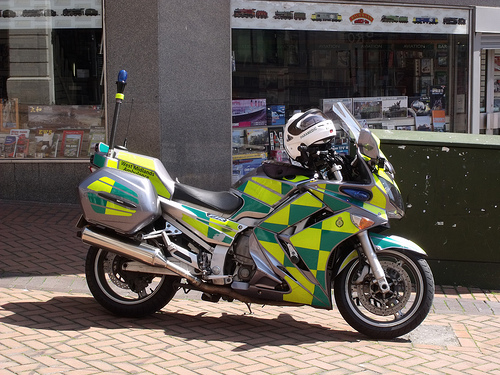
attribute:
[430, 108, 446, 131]
box — orange, on display, displayed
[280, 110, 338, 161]
helmet — white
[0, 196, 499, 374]
ground — cobblestone, brick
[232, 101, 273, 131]
magazine — displayed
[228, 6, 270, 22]
train — red, decorative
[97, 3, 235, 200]
pillar — concrete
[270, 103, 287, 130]
box — blue, displayed, on display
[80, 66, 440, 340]
motorbike — parked, yellow, green